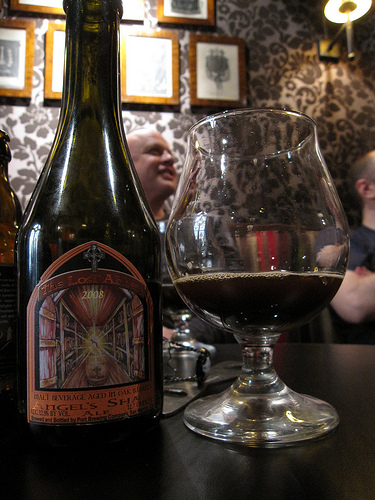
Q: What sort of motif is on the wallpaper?
A: A black and white floral motif.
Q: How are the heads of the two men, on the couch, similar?
A: They're both bald, on top.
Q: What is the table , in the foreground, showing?
A: Wine bottles, glasses, with wine, and a bottle-cap opener.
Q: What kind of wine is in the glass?
A: Red wine.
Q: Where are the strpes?
A: On the couch.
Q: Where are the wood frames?
A: On the row of pictures, on the wall.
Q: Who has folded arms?
A: A man with a fringe of hair, surrounding around his bald pate.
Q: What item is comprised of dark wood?
A: The table, holding the wine glasses and bottles?.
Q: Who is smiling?
A: A hairless, young man, who is looking up.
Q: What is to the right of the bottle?
A: Glass.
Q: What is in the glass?
A: Wine.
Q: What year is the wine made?
A: 2008.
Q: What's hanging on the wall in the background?
A: Photo frames.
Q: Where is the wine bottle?
A: On the table.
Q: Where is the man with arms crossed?
A: On the right.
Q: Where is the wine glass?
A: Next to the wine bottle on the table.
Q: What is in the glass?
A: Red wine.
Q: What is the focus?
A: Alcoholic drink in glass.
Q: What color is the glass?
A: Green.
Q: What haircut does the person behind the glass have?
A: Bald.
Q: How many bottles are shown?
A: 2.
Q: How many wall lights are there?
A: 1.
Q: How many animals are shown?
A: 0.